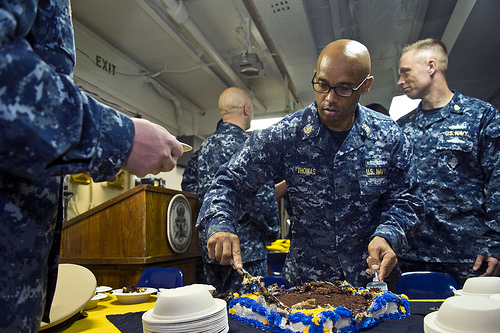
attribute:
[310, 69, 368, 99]
glasses — black 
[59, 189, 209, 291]
desk — wooden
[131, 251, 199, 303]
chair — blue 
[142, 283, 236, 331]
bowls — grouped, paper, stacked, upside down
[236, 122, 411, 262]
man's uniform — blue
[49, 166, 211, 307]
podium — brown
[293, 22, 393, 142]
head — SHINY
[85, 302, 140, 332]
tablecloth — blue 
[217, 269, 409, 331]
cake — WHITE 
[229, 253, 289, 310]
knife — cutting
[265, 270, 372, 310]
frosting — colorful